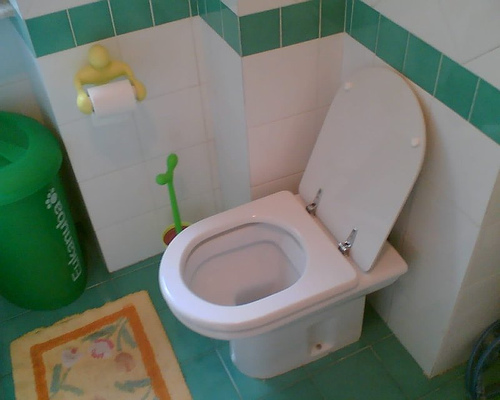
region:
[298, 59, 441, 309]
white porcelain toilet lid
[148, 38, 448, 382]
white porcelain toilet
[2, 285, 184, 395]
decorative bathroom floor mat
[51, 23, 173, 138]
toilet paper roll dispenser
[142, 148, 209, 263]
decorative toilet plunger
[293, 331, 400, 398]
green porcelain bathroom floor tile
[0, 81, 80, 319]
plastic bathroom trash bin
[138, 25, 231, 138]
white porcelain wall tiles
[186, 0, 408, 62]
green accented porcelain tiles for wall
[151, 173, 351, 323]
white porcelain toilet seat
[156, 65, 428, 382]
A white toilet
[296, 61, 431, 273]
A white toilet lid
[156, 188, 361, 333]
A white toilet seat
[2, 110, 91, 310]
A green trash can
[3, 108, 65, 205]
A green lid of a trash can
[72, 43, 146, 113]
A yellow toilet paper holder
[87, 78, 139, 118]
A roll of white toilet paper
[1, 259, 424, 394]
A green tile bathroom floor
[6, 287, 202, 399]
A bathroom throw rug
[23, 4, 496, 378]
Green and white tile on a bathroom wall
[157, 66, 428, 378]
a white toilet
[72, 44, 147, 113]
a yellow toilet paper dispenser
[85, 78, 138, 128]
a roll of toilet paper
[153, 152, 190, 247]
a toilet plunger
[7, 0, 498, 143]
a row of green tiles on the walls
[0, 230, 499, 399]
a green tile floor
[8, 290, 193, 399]
a small rug on the floor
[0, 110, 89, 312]
a green wastebasket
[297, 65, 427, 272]
the toilet seat cover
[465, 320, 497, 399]
a dark green object in the lower-right corner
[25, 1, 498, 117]
square green ceramic tiles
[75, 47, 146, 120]
yellow holder for toilet paper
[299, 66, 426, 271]
open lid of toilet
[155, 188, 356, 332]
white seat of toilet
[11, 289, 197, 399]
yellow and orange rug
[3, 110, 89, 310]
green can with white word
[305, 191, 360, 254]
silver hardware on toilet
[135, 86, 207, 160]
square white bathroom tile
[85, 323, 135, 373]
two flowers on rug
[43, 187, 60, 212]
white pawprint on green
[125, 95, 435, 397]
white toilet in bathroom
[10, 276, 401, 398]
rug on floor in front of toilet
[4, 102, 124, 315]
green plastic container with top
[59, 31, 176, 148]
yellow toilet paper holder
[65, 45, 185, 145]
white toilet paper on yellow holder on wall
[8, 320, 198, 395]
flowers on orange rug on floor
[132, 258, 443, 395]
green tile on floor around toilet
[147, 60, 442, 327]
lid on toilet is open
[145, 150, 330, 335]
green handle next to toilet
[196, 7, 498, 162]
white tile wall with green tile trim